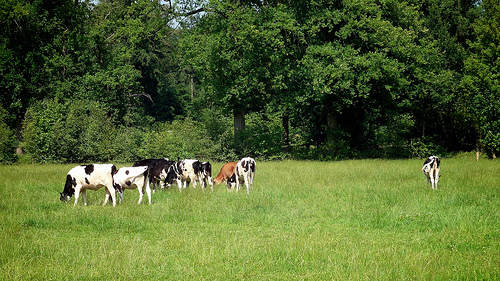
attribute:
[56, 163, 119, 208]
cow — black and white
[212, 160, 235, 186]
cow — brown 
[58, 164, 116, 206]
cow — black and white, eating 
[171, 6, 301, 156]
tree — big 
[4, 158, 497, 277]
field — grassy 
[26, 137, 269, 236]
cows — eating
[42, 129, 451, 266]
field with cows — grass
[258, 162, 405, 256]
field of grass — green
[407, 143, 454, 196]
cow by itself — black, white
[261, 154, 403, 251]
green cow pasture — grassy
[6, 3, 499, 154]
forested area — dense, green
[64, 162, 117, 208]
view of a cow — side